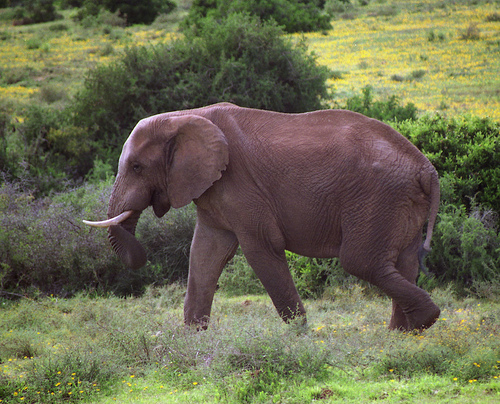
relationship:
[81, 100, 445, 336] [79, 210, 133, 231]
elephant has tusk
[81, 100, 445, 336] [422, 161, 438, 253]
elephant has tail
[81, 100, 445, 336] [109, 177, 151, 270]
elephant has trunk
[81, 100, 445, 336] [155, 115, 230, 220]
elephant has ear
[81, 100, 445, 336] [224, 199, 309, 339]
elephant has leg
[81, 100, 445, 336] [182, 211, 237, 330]
elephant has leg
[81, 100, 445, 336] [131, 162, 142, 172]
elephant has eye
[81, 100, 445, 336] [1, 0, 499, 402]
elephant in grass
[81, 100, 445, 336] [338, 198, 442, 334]
elephant has leg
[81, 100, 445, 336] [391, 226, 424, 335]
elephant has leg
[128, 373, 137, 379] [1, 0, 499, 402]
flower in grass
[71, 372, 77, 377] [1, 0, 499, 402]
flower in grass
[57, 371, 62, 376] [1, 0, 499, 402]
flower in grass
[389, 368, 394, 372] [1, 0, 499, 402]
flower in grass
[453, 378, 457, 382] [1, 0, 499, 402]
flower in grass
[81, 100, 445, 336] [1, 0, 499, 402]
elephant on top of grass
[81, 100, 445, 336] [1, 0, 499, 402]
elephant standing in grass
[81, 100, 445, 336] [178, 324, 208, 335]
elephant has foot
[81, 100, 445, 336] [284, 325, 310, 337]
elephant has foot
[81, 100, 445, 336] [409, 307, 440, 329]
elephant has foot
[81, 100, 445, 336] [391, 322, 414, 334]
elephant has foot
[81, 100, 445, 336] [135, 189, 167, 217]
elephant has mouth